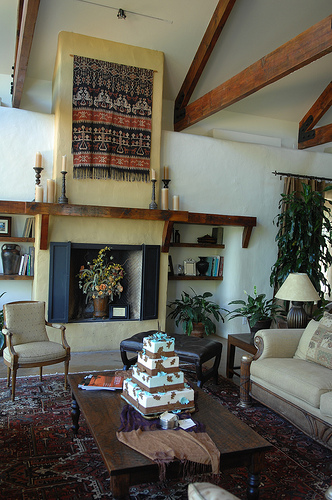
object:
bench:
[119, 330, 223, 389]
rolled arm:
[238, 328, 307, 409]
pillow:
[292, 311, 331, 371]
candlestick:
[32, 165, 171, 210]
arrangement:
[76, 246, 127, 318]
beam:
[172, 0, 332, 151]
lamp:
[274, 272, 321, 328]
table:
[225, 333, 258, 379]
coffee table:
[67, 370, 273, 499]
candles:
[35, 185, 44, 203]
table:
[0, 197, 257, 253]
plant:
[224, 285, 287, 328]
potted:
[75, 246, 127, 319]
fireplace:
[44, 212, 162, 324]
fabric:
[70, 56, 153, 184]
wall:
[21, 91, 51, 152]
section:
[143, 332, 176, 360]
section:
[121, 383, 196, 419]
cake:
[120, 330, 196, 420]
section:
[137, 351, 179, 373]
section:
[129, 354, 185, 390]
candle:
[148, 167, 158, 211]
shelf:
[0, 199, 256, 228]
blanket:
[116, 404, 221, 483]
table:
[179, 334, 221, 341]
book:
[78, 373, 124, 391]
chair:
[2, 300, 71, 401]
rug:
[0, 435, 78, 500]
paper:
[112, 307, 125, 316]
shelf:
[44, 318, 162, 354]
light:
[116, 7, 126, 20]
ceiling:
[31, 0, 187, 80]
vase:
[196, 256, 210, 277]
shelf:
[168, 274, 224, 280]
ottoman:
[206, 376, 224, 394]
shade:
[274, 271, 322, 301]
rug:
[0, 356, 332, 499]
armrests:
[7, 332, 19, 363]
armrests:
[59, 325, 71, 351]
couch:
[237, 311, 332, 450]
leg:
[236, 354, 254, 408]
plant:
[165, 285, 230, 335]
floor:
[0, 342, 332, 500]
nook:
[160, 220, 225, 339]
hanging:
[69, 54, 157, 184]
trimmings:
[147, 332, 175, 342]